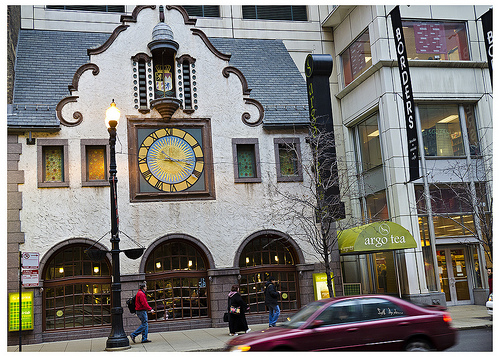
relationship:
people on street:
[131, 277, 278, 342] [99, 312, 491, 351]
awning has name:
[333, 223, 420, 255] [364, 232, 410, 247]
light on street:
[104, 101, 120, 127] [99, 312, 491, 351]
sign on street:
[23, 252, 40, 289] [99, 312, 491, 351]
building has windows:
[4, 2, 490, 345] [337, 23, 490, 301]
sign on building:
[390, 5, 426, 186] [4, 2, 490, 345]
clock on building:
[131, 119, 215, 201] [4, 2, 490, 345]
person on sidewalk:
[131, 277, 278, 342] [67, 293, 449, 356]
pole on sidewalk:
[111, 102, 135, 349] [67, 293, 449, 356]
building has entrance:
[4, 2, 490, 345] [339, 250, 372, 302]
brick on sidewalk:
[343, 282, 363, 303] [67, 293, 449, 356]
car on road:
[231, 292, 461, 347] [222, 323, 489, 352]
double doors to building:
[438, 251, 472, 305] [337, 23, 490, 301]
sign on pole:
[23, 252, 40, 289] [111, 102, 135, 349]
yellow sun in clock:
[150, 133, 191, 183] [131, 119, 215, 201]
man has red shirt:
[129, 285, 155, 343] [134, 289, 150, 315]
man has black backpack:
[129, 285, 155, 343] [126, 298, 139, 309]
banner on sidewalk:
[390, 5, 426, 186] [67, 293, 449, 356]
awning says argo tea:
[333, 223, 420, 255] [363, 236, 405, 248]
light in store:
[423, 213, 494, 269] [363, 186, 499, 316]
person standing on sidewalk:
[220, 283, 249, 336] [67, 293, 449, 356]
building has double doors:
[337, 23, 490, 301] [438, 251, 472, 305]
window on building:
[337, 23, 490, 301] [4, 2, 490, 345]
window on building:
[40, 142, 66, 185] [4, 2, 490, 345]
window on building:
[83, 142, 104, 184] [4, 2, 490, 345]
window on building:
[234, 140, 255, 180] [4, 2, 490, 345]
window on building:
[278, 140, 300, 177] [4, 2, 490, 345]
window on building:
[333, 24, 370, 92] [4, 2, 490, 345]